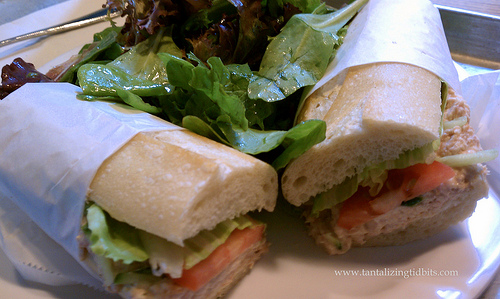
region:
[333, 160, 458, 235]
the tomato is red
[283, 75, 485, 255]
the tomato is between the bread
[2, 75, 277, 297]
the sandwich half is wrapped in white paper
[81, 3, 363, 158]
greens between the sandwiches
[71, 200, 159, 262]
lettuce on the sandwich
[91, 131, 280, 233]
the bread is brown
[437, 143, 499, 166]
a piece of onion by the tomato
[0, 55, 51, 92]
a purple leaf behind the sandwich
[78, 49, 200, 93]
the leaf is shiny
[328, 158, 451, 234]
a slice of tomato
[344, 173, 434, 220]
a tomatoe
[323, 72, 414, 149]
the bread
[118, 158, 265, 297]
a sandwhich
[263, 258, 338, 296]
the plate is white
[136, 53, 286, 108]
a salad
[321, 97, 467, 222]
half of a sandwhich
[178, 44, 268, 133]
the leaves are green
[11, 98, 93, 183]
white paper on the sandwhich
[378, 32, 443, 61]
the wrapping on the sandwhich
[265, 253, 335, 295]
the plate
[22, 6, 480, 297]
Lunch on a plate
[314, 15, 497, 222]
A sandwich in wrapping paper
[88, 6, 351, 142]
A salad on a plate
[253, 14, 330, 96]
A piece of spinach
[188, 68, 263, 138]
A piece of lettuce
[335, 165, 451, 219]
A slice of tomato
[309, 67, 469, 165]
A piece of brea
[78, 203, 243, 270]
Lettuce on a sandwich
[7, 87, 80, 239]
White paper for wrapping sandwiches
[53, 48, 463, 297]
A sandwich cut in half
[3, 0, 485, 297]
Two sandwiches are on the plate.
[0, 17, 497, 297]
The plate is white.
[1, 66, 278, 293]
Part of the sandwich is wrapped in paper.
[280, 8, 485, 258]
The other sandwich is also wrapped in paper.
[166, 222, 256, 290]
A slice of tomato is on the sandwich.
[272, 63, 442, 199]
The sandwhich has white bread on the top.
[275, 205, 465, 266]
A shadow of the sandwich is on the plate.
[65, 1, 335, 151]
A salad is in between the two sandwiches.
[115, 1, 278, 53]
Some leaves in the salad are purplish green.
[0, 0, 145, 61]
A utensil handle on the plate.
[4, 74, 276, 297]
sandwich wrapped in white paper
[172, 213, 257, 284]
slice of tomato in sandwich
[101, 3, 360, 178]
green leaves in salad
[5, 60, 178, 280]
piece of white paper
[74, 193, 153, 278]
lettuce in sandwich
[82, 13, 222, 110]
raw green spinach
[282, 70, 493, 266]
sandwich made of baguette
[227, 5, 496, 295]
sandwich on white plate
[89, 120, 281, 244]
piece of white bread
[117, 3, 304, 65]
red leaves in salad